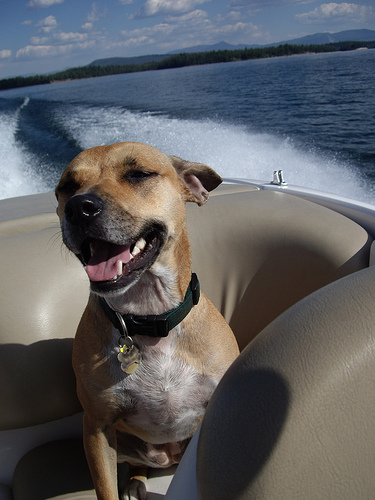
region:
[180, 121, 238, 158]
the water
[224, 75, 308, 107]
the water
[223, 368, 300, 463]
shadow on the seat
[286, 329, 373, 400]
a seat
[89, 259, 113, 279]
the dogs tongue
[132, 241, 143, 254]
the dogs teeth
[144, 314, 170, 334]
the dogs collar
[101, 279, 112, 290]
the dogs lip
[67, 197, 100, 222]
the dogs nose is black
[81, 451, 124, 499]
the dogs leg is brown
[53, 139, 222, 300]
Head of happy dog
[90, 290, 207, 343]
Part of collar on brown dog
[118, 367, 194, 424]
White chest of brown dog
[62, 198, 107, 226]
Black nose of happy dog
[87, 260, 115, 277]
Part of dog's pink tongue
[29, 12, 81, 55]
White Clouds in summer sky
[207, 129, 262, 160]
Churning white ocean surf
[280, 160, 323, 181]
Churning white ocean surf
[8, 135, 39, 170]
Churning white ocean surf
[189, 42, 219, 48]
hazy hills in background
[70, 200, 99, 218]
a dog's black nose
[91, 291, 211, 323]
collar is black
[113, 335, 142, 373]
dog tags on the collar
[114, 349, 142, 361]
dog tag is of a bone shape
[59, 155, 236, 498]
a tan and white dog sitting on a boat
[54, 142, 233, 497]
a tan and white dog sitting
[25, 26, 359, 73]
the skyline on the horizon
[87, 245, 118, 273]
dog's tongue is pink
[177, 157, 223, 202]
dog's left ear is pointy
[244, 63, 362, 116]
the blue calm waters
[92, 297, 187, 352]
the collar is green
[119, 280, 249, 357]
the collar is green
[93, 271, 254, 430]
the collar is green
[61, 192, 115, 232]
the nose is black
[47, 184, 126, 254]
the nose is black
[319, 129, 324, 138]
part of the water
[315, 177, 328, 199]
part of the ocean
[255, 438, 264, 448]
edge of a seat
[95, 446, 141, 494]
edge of a leg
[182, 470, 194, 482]
part of a plate